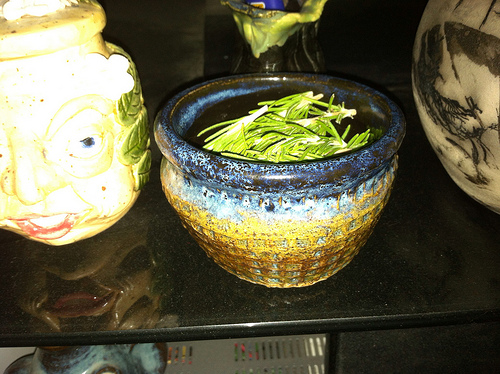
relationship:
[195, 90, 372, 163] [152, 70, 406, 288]
grass in a vase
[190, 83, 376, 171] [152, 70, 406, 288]
grass in a vase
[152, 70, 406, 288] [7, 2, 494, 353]
vase on table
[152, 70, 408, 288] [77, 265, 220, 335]
vase on table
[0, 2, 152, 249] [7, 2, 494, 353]
vase on table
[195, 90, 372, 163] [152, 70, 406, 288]
grass in vase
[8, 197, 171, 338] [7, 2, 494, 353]
reflection on table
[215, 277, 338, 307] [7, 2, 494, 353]
reflection on table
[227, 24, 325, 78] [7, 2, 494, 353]
reflection on table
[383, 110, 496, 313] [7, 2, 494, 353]
reflection on table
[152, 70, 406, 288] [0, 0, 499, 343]
vase on shelf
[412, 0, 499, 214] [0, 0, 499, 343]
ceramic on shelf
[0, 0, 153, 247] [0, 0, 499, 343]
ceramic on shelf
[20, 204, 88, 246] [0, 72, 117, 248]
lips on face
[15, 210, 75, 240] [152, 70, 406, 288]
mouth on vase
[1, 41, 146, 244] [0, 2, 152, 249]
face on vase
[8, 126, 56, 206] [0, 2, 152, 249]
nose on vase